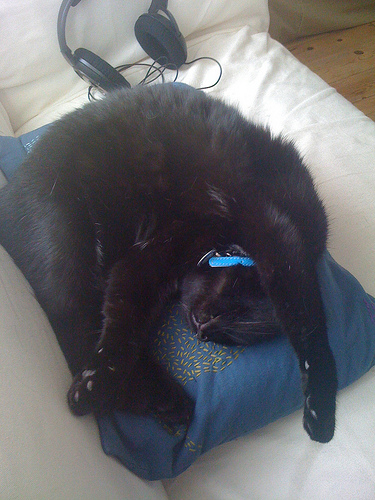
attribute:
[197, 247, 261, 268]
collar — blue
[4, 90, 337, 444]
cat — black, laying, sleeping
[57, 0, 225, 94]
headphones — sitting, black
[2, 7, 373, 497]
couch — white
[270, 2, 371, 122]
floor — wooden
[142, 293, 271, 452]
pattern — yellow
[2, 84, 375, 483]
pillow — blue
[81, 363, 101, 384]
pads — black